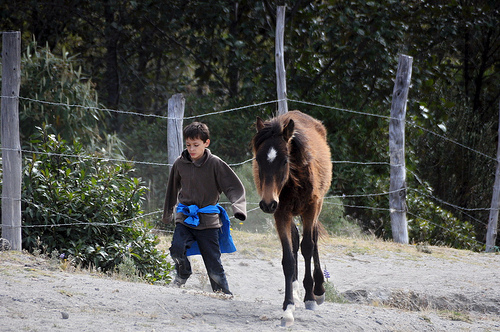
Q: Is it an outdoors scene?
A: Yes, it is outdoors.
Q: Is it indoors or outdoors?
A: It is outdoors.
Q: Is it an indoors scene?
A: No, it is outdoors.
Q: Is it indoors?
A: No, it is outdoors.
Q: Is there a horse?
A: Yes, there is a horse.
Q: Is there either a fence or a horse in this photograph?
A: Yes, there is a horse.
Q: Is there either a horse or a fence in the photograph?
A: Yes, there is a horse.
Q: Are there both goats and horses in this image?
A: No, there is a horse but no goats.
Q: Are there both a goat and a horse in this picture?
A: No, there is a horse but no goats.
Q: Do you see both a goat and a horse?
A: No, there is a horse but no goats.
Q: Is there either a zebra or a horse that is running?
A: Yes, the horse is running.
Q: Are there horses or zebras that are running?
A: Yes, the horse is running.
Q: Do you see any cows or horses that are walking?
A: Yes, the horse is walking.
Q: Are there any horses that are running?
A: Yes, there is a horse that is running.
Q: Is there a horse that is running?
A: Yes, there is a horse that is running.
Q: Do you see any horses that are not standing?
A: Yes, there is a horse that is running .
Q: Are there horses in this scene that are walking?
A: Yes, there is a horse that is walking.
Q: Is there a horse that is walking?
A: Yes, there is a horse that is walking.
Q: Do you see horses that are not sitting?
A: Yes, there is a horse that is walking .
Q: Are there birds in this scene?
A: No, there are no birds.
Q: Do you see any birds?
A: No, there are no birds.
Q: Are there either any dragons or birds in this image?
A: No, there are no birds or dragons.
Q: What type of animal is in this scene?
A: The animal is a horse.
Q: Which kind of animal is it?
A: The animal is a horse.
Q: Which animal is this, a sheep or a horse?
A: This is a horse.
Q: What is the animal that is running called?
A: The animal is a horse.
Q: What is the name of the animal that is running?
A: The animal is a horse.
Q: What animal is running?
A: The animal is a horse.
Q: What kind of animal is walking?
A: The animal is a horse.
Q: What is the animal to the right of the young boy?
A: The animal is a horse.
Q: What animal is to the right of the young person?
A: The animal is a horse.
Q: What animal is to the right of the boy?
A: The animal is a horse.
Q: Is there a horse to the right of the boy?
A: Yes, there is a horse to the right of the boy.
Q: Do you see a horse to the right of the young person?
A: Yes, there is a horse to the right of the boy.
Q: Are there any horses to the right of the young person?
A: Yes, there is a horse to the right of the boy.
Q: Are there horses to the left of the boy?
A: No, the horse is to the right of the boy.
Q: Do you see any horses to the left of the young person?
A: No, the horse is to the right of the boy.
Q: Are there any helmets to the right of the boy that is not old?
A: No, there is a horse to the right of the boy.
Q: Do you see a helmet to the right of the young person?
A: No, there is a horse to the right of the boy.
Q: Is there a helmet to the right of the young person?
A: No, there is a horse to the right of the boy.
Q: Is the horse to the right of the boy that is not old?
A: Yes, the horse is to the right of the boy.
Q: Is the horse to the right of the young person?
A: Yes, the horse is to the right of the boy.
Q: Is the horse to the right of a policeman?
A: No, the horse is to the right of the boy.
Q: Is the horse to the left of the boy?
A: No, the horse is to the right of the boy.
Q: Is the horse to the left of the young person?
A: No, the horse is to the right of the boy.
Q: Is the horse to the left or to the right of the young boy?
A: The horse is to the right of the boy.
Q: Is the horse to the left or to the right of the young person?
A: The horse is to the right of the boy.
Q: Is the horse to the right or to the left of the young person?
A: The horse is to the right of the boy.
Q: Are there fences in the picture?
A: Yes, there is a fence.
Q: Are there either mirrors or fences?
A: Yes, there is a fence.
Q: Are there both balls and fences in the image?
A: No, there is a fence but no balls.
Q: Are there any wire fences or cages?
A: Yes, there is a wire fence.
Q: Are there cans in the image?
A: No, there are no cans.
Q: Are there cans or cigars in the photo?
A: No, there are no cans or cigars.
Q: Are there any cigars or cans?
A: No, there are no cans or cigars.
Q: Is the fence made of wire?
A: Yes, the fence is made of wire.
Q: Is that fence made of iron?
A: No, the fence is made of wire.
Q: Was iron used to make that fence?
A: No, the fence is made of wire.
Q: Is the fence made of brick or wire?
A: The fence is made of wire.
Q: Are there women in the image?
A: No, there are no women.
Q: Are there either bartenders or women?
A: No, there are no women or bartenders.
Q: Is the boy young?
A: Yes, the boy is young.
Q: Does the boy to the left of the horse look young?
A: Yes, the boy is young.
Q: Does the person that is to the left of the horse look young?
A: Yes, the boy is young.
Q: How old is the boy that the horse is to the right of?
A: The boy is young.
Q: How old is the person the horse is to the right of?
A: The boy is young.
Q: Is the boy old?
A: No, the boy is young.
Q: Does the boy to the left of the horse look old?
A: No, the boy is young.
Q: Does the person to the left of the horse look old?
A: No, the boy is young.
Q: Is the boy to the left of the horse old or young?
A: The boy is young.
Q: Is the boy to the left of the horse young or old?
A: The boy is young.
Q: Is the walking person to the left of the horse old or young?
A: The boy is young.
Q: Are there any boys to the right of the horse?
A: No, the boy is to the left of the horse.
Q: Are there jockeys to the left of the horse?
A: No, there is a boy to the left of the horse.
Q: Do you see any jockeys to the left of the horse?
A: No, there is a boy to the left of the horse.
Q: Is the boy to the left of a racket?
A: No, the boy is to the left of the horse.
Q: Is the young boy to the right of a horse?
A: No, the boy is to the left of a horse.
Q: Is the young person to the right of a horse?
A: No, the boy is to the left of a horse.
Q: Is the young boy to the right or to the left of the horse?
A: The boy is to the left of the horse.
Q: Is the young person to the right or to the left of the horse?
A: The boy is to the left of the horse.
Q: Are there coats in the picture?
A: Yes, there is a coat.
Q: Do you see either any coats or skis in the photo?
A: Yes, there is a coat.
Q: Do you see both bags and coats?
A: No, there is a coat but no bags.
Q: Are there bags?
A: No, there are no bags.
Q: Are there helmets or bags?
A: No, there are no bags or helmets.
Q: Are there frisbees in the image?
A: No, there are no frisbees.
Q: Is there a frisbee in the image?
A: No, there are no frisbees.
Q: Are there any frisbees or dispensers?
A: No, there are no frisbees or dispensers.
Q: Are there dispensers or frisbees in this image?
A: No, there are no frisbees or dispensers.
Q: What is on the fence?
A: The wire is on the fence.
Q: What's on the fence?
A: The wire is on the fence.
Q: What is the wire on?
A: The wire is on the fence.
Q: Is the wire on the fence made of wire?
A: Yes, the wire is on the fence.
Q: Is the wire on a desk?
A: No, the wire is on the fence.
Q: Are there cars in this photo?
A: No, there are no cars.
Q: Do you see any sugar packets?
A: No, there are no sugar packets.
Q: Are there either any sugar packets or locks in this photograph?
A: No, there are no sugar packets or locks.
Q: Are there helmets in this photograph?
A: No, there are no helmets.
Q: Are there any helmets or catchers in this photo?
A: No, there are no helmets or catchers.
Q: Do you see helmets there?
A: No, there are no helmets.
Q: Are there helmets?
A: No, there are no helmets.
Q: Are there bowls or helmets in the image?
A: No, there are no helmets or bowls.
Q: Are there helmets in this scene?
A: No, there are no helmets.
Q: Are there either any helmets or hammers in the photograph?
A: No, there are no helmets or hammers.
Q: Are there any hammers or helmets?
A: No, there are no helmets or hammers.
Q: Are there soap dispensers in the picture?
A: No, there are no soap dispensers.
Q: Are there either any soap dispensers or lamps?
A: No, there are no soap dispensers or lamps.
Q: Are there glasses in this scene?
A: No, there are no glasses.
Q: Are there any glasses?
A: No, there are no glasses.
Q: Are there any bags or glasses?
A: No, there are no glasses or bags.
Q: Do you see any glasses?
A: No, there are no glasses.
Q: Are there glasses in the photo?
A: No, there are no glasses.